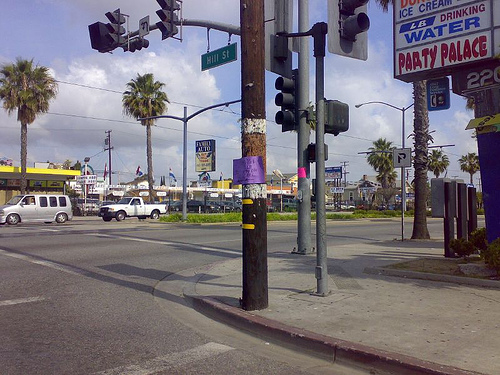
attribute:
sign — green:
[201, 42, 235, 75]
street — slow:
[3, 222, 234, 374]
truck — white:
[98, 196, 171, 222]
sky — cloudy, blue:
[62, 52, 189, 82]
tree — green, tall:
[2, 58, 56, 191]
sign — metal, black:
[391, 147, 414, 238]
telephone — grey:
[428, 178, 454, 255]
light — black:
[275, 68, 299, 138]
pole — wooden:
[242, 0, 269, 306]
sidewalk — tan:
[204, 312, 439, 363]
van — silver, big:
[2, 192, 74, 225]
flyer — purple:
[234, 155, 262, 184]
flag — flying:
[167, 169, 180, 183]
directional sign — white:
[138, 15, 151, 39]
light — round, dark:
[275, 111, 295, 127]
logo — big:
[396, 3, 486, 49]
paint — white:
[240, 118, 266, 136]